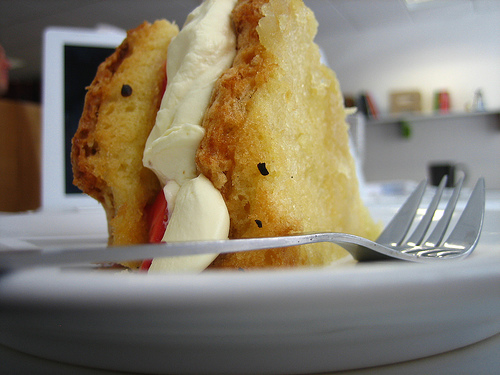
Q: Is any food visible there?
A: Yes, there is food.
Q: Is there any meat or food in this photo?
A: Yes, there is food.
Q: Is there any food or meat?
A: Yes, there is food.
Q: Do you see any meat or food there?
A: Yes, there is food.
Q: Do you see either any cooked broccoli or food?
A: Yes, there is cooked food.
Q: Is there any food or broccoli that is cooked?
A: Yes, the food is cooked.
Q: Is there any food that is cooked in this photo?
A: Yes, there is cooked food.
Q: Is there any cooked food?
A: Yes, there is cooked food.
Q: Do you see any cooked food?
A: Yes, there is cooked food.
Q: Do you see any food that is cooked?
A: Yes, there is food that is cooked.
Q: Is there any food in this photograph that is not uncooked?
A: Yes, there is cooked food.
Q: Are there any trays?
A: No, there are no trays.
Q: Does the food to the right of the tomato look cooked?
A: Yes, the food is cooked.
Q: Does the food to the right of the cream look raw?
A: No, the food is cooked.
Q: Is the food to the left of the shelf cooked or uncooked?
A: The food is cooked.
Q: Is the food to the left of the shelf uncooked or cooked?
A: The food is cooked.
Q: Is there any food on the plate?
A: Yes, there is food on the plate.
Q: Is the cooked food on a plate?
A: Yes, the food is on a plate.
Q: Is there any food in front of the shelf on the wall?
A: Yes, there is food in front of the shelf.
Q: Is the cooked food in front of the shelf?
A: Yes, the food is in front of the shelf.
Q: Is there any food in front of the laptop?
A: Yes, there is food in front of the laptop.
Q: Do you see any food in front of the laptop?
A: Yes, there is food in front of the laptop.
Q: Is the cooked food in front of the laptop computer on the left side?
A: Yes, the food is in front of the laptop computer.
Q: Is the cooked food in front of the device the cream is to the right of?
A: Yes, the food is in front of the laptop computer.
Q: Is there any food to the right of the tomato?
A: Yes, there is food to the right of the tomato.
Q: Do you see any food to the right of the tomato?
A: Yes, there is food to the right of the tomato.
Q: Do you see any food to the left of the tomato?
A: No, the food is to the right of the tomato.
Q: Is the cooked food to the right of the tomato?
A: Yes, the food is to the right of the tomato.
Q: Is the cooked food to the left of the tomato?
A: No, the food is to the right of the tomato.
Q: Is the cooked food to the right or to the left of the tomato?
A: The food is to the right of the tomato.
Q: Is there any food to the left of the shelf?
A: Yes, there is food to the left of the shelf.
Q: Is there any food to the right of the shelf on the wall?
A: No, the food is to the left of the shelf.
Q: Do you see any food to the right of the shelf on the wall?
A: No, the food is to the left of the shelf.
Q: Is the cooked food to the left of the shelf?
A: Yes, the food is to the left of the shelf.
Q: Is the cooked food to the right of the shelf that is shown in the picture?
A: No, the food is to the left of the shelf.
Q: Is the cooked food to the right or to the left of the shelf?
A: The food is to the left of the shelf.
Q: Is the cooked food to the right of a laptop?
A: Yes, the food is to the right of a laptop.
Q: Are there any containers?
A: No, there are no containers.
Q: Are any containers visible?
A: No, there are no containers.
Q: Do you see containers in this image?
A: No, there are no containers.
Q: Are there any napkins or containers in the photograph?
A: No, there are no containers or napkins.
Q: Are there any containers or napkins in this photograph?
A: No, there are no containers or napkins.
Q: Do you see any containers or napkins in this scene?
A: No, there are no containers or napkins.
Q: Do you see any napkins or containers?
A: No, there are no containers or napkins.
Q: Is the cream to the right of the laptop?
A: Yes, the cream is to the right of the laptop.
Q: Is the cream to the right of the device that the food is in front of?
A: Yes, the cream is to the right of the laptop.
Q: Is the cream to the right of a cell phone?
A: No, the cream is to the right of the laptop.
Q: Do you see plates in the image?
A: Yes, there is a plate.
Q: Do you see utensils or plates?
A: Yes, there is a plate.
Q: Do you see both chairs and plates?
A: No, there is a plate but no chairs.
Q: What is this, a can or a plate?
A: This is a plate.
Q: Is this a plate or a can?
A: This is a plate.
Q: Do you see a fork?
A: Yes, there is a fork.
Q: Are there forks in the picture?
A: Yes, there is a fork.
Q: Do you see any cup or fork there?
A: Yes, there is a fork.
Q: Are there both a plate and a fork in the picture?
A: Yes, there are both a fork and a plate.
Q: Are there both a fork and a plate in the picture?
A: Yes, there are both a fork and a plate.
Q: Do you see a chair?
A: No, there are no chairs.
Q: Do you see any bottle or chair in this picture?
A: No, there are no chairs or bottles.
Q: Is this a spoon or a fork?
A: This is a fork.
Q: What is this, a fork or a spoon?
A: This is a fork.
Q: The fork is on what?
A: The fork is on the plate.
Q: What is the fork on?
A: The fork is on the plate.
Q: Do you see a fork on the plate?
A: Yes, there is a fork on the plate.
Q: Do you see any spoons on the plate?
A: No, there is a fork on the plate.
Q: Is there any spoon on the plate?
A: No, there is a fork on the plate.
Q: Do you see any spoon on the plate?
A: No, there is a fork on the plate.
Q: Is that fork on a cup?
A: No, the fork is on the plate.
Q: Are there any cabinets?
A: No, there are no cabinets.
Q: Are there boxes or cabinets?
A: No, there are no cabinets or boxes.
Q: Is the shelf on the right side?
A: Yes, the shelf is on the right of the image.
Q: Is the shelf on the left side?
A: No, the shelf is on the right of the image.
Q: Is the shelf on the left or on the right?
A: The shelf is on the right of the image.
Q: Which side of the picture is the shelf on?
A: The shelf is on the right of the image.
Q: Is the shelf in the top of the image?
A: Yes, the shelf is in the top of the image.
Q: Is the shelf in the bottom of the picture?
A: No, the shelf is in the top of the image.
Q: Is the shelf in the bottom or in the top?
A: The shelf is in the top of the image.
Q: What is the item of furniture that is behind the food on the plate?
A: The piece of furniture is a shelf.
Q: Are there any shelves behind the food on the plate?
A: Yes, there is a shelf behind the food.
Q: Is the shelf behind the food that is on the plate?
A: Yes, the shelf is behind the food.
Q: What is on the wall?
A: The shelf is on the wall.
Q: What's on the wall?
A: The shelf is on the wall.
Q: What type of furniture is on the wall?
A: The piece of furniture is a shelf.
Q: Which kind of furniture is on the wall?
A: The piece of furniture is a shelf.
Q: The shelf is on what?
A: The shelf is on the wall.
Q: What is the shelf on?
A: The shelf is on the wall.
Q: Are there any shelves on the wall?
A: Yes, there is a shelf on the wall.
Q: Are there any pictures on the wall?
A: No, there is a shelf on the wall.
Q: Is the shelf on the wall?
A: Yes, the shelf is on the wall.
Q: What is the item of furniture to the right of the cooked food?
A: The piece of furniture is a shelf.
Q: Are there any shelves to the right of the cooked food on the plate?
A: Yes, there is a shelf to the right of the food.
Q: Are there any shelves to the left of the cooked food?
A: No, the shelf is to the right of the food.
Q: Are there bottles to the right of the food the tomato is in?
A: No, there is a shelf to the right of the food.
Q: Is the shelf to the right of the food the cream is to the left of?
A: Yes, the shelf is to the right of the food.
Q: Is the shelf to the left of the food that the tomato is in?
A: No, the shelf is to the right of the food.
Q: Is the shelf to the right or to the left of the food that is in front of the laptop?
A: The shelf is to the right of the food.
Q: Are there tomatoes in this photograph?
A: Yes, there is a tomato.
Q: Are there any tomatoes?
A: Yes, there is a tomato.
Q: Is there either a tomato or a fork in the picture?
A: Yes, there is a tomato.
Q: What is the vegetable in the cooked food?
A: The vegetable is a tomato.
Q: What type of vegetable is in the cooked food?
A: The vegetable is a tomato.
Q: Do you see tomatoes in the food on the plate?
A: Yes, there is a tomato in the food.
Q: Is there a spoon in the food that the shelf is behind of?
A: No, there is a tomato in the food.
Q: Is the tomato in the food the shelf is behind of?
A: Yes, the tomato is in the food.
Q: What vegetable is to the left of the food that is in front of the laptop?
A: The vegetable is a tomato.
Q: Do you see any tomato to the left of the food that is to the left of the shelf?
A: Yes, there is a tomato to the left of the food.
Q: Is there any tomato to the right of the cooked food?
A: No, the tomato is to the left of the food.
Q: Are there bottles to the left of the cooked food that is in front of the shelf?
A: No, there is a tomato to the left of the food.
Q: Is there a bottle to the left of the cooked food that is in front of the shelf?
A: No, there is a tomato to the left of the food.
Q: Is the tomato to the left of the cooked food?
A: Yes, the tomato is to the left of the food.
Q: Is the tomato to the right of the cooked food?
A: No, the tomato is to the left of the food.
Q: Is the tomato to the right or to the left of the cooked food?
A: The tomato is to the left of the food.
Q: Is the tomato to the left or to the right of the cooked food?
A: The tomato is to the left of the food.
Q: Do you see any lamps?
A: No, there are no lamps.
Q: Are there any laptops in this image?
A: Yes, there is a laptop.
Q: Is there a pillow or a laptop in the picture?
A: Yes, there is a laptop.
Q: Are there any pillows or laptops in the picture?
A: Yes, there is a laptop.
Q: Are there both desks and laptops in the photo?
A: No, there is a laptop but no desks.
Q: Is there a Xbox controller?
A: No, there are no Xbox controllers.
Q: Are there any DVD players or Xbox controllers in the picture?
A: No, there are no Xbox controllers or DVD players.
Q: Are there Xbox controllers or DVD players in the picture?
A: No, there are no Xbox controllers or DVD players.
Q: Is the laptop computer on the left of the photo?
A: Yes, the laptop computer is on the left of the image.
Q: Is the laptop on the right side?
A: No, the laptop is on the left of the image.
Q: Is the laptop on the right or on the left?
A: The laptop is on the left of the image.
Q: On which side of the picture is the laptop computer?
A: The laptop computer is on the left of the image.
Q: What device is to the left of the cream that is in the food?
A: The device is a laptop.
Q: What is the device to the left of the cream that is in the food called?
A: The device is a laptop.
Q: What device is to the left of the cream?
A: The device is a laptop.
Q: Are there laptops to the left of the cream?
A: Yes, there is a laptop to the left of the cream.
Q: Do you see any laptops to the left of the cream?
A: Yes, there is a laptop to the left of the cream.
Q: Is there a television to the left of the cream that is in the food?
A: No, there is a laptop to the left of the cream.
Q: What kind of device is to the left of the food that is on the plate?
A: The device is a laptop.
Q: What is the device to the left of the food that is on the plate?
A: The device is a laptop.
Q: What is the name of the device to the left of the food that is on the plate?
A: The device is a laptop.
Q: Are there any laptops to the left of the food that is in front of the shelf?
A: Yes, there is a laptop to the left of the food.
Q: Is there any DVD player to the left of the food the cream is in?
A: No, there is a laptop to the left of the food.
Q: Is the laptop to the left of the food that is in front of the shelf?
A: Yes, the laptop is to the left of the food.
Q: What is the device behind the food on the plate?
A: The device is a laptop.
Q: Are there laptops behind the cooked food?
A: Yes, there is a laptop behind the food.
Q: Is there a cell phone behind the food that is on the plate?
A: No, there is a laptop behind the food.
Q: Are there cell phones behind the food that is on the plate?
A: No, there is a laptop behind the food.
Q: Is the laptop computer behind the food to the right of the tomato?
A: Yes, the laptop computer is behind the food.